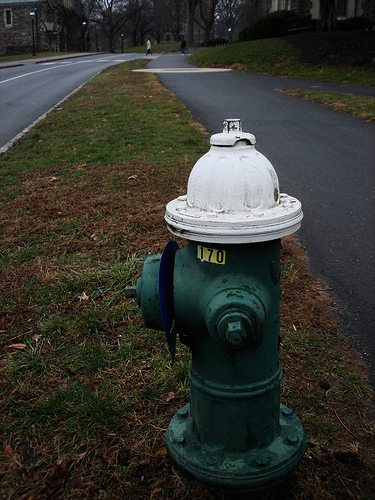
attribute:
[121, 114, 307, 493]
hydrant — white, green, here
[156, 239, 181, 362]
disk — blue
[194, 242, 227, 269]
number — black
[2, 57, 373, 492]
grass — here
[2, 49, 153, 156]
road — tarmac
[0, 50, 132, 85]
line — white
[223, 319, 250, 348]
bolt — large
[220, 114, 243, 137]
bolt — large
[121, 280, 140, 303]
bolt — large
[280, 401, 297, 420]
bolt — large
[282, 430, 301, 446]
bolt — large, green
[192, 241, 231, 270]
sticker — yellow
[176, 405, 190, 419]
bolt — green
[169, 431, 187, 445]
bolt — gre4en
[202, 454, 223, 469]
bolt — green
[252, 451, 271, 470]
bolt — green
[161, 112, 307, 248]
cap — white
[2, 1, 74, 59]
building — here, country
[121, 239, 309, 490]
base — green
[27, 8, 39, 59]
lamp — black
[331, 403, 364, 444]
twig — brown